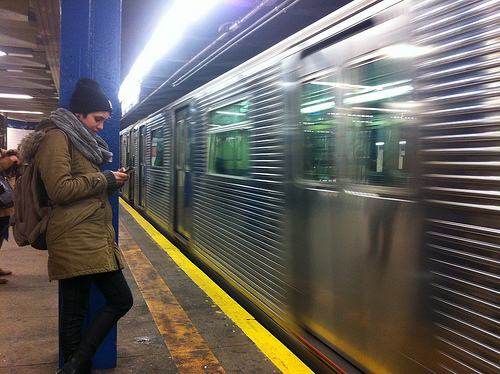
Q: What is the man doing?
A: Texting.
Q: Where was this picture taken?
A: In a subway.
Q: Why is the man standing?
A: To wait for train.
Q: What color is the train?
A: Gray.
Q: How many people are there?
A: One.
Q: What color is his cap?
A: Black.